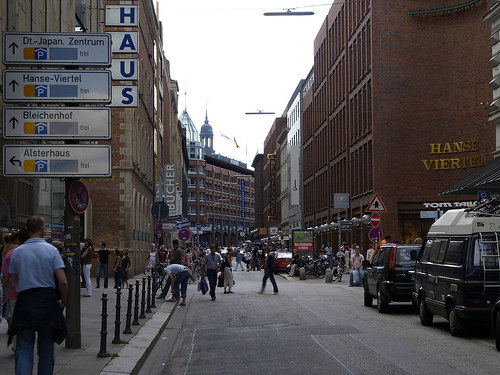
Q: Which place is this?
A: It is a street.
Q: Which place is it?
A: It is a street.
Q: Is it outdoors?
A: Yes, it is outdoors.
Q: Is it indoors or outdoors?
A: It is outdoors.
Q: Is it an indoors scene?
A: No, it is outdoors.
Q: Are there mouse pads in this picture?
A: No, there are no mouse pads.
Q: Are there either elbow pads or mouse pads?
A: No, there are no mouse pads or elbow pads.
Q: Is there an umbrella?
A: No, there are no umbrellas.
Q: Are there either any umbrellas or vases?
A: No, there are no umbrellas or vases.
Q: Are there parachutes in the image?
A: No, there are no parachutes.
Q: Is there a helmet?
A: No, there are no helmets.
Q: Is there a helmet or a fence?
A: No, there are no helmets or fences.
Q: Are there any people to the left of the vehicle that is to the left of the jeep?
A: Yes, there is a person to the left of the vehicle.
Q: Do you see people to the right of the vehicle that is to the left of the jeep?
A: No, the person is to the left of the vehicle.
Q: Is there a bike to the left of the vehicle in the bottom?
A: No, there is a person to the left of the vehicle.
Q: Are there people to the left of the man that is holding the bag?
A: Yes, there is a person to the left of the man.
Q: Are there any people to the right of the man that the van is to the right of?
A: No, the person is to the left of the man.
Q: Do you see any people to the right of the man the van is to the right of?
A: No, the person is to the left of the man.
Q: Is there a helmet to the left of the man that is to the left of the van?
A: No, there is a person to the left of the man.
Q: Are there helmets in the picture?
A: No, there are no helmets.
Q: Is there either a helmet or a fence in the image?
A: No, there are no helmets or fences.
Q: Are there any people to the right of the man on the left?
A: Yes, there is a person to the right of the man.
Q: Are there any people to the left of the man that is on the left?
A: No, the person is to the right of the man.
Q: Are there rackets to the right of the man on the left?
A: No, there is a person to the right of the man.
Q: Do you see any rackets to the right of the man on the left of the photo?
A: No, there is a person to the right of the man.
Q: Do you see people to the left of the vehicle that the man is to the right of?
A: Yes, there is a person to the left of the vehicle.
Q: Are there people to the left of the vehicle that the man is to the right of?
A: Yes, there is a person to the left of the vehicle.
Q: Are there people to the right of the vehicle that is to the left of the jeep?
A: No, the person is to the left of the vehicle.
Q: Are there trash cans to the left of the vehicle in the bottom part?
A: No, there is a person to the left of the vehicle.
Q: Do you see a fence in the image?
A: No, there are no fences.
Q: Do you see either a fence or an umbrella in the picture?
A: No, there are no fences or umbrellas.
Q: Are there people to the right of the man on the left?
A: Yes, there are people to the right of the man.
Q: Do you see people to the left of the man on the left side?
A: No, the people are to the right of the man.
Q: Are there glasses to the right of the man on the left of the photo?
A: No, there are people to the right of the man.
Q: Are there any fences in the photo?
A: No, there are no fences.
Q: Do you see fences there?
A: No, there are no fences.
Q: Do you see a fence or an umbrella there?
A: No, there are no fences or umbrellas.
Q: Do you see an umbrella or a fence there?
A: No, there are no fences or umbrellas.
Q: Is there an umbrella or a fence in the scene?
A: No, there are no fences or umbrellas.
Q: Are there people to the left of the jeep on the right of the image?
A: Yes, there are people to the left of the jeep.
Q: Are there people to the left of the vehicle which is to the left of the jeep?
A: Yes, there are people to the left of the vehicle.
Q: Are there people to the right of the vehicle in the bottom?
A: No, the people are to the left of the vehicle.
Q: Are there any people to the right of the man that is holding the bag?
A: No, the people are to the left of the man.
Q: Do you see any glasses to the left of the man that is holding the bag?
A: No, there are people to the left of the man.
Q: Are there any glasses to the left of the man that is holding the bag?
A: No, there are people to the left of the man.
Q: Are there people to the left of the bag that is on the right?
A: Yes, there are people to the left of the bag.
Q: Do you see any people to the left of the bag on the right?
A: Yes, there are people to the left of the bag.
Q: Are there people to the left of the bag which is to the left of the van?
A: Yes, there are people to the left of the bag.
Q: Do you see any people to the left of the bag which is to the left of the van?
A: Yes, there are people to the left of the bag.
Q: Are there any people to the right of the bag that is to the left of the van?
A: No, the people are to the left of the bag.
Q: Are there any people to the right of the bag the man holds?
A: No, the people are to the left of the bag.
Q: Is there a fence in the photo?
A: No, there are no fences.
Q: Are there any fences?
A: No, there are no fences.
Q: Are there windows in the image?
A: Yes, there is a window.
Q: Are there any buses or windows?
A: Yes, there is a window.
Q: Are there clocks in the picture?
A: No, there are no clocks.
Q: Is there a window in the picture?
A: Yes, there is a window.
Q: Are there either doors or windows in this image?
A: Yes, there is a window.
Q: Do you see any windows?
A: Yes, there is a window.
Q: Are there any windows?
A: Yes, there is a window.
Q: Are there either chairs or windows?
A: Yes, there is a window.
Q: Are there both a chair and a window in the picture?
A: No, there is a window but no chairs.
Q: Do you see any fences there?
A: No, there are no fences.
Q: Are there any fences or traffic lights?
A: No, there are no fences or traffic lights.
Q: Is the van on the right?
A: Yes, the van is on the right of the image.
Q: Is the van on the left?
A: No, the van is on the right of the image.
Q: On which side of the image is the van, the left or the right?
A: The van is on the right of the image.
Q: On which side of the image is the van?
A: The van is on the right of the image.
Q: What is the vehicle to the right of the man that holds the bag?
A: The vehicle is a van.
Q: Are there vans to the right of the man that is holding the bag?
A: Yes, there is a van to the right of the man.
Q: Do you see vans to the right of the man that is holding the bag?
A: Yes, there is a van to the right of the man.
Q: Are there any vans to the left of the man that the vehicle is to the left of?
A: No, the van is to the right of the man.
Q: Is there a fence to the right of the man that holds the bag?
A: No, there is a van to the right of the man.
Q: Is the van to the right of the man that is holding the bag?
A: Yes, the van is to the right of the man.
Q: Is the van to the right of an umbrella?
A: No, the van is to the right of the man.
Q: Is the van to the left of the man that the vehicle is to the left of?
A: No, the van is to the right of the man.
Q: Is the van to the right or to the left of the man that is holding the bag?
A: The van is to the right of the man.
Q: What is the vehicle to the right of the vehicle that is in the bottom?
A: The vehicle is a van.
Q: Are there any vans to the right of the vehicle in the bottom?
A: Yes, there is a van to the right of the vehicle.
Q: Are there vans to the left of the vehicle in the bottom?
A: No, the van is to the right of the vehicle.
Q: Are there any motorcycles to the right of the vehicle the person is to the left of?
A: No, there is a van to the right of the vehicle.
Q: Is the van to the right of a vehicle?
A: Yes, the van is to the right of a vehicle.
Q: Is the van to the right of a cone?
A: No, the van is to the right of a vehicle.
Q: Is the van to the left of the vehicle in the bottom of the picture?
A: No, the van is to the right of the vehicle.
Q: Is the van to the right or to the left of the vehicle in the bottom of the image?
A: The van is to the right of the vehicle.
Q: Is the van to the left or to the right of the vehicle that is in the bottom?
A: The van is to the right of the vehicle.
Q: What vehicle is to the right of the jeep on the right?
A: The vehicle is a van.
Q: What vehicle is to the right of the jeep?
A: The vehicle is a van.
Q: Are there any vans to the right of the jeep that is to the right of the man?
A: Yes, there is a van to the right of the jeep.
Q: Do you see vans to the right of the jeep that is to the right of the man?
A: Yes, there is a van to the right of the jeep.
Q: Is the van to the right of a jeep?
A: Yes, the van is to the right of a jeep.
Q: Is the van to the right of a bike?
A: No, the van is to the right of a jeep.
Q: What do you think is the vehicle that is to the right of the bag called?
A: The vehicle is a van.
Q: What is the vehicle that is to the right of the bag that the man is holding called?
A: The vehicle is a van.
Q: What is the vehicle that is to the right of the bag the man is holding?
A: The vehicle is a van.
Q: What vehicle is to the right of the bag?
A: The vehicle is a van.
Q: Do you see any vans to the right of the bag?
A: Yes, there is a van to the right of the bag.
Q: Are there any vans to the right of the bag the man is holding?
A: Yes, there is a van to the right of the bag.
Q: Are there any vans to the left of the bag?
A: No, the van is to the right of the bag.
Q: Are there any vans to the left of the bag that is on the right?
A: No, the van is to the right of the bag.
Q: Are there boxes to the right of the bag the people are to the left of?
A: No, there is a van to the right of the bag.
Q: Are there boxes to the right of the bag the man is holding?
A: No, there is a van to the right of the bag.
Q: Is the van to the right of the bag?
A: Yes, the van is to the right of the bag.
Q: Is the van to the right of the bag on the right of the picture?
A: Yes, the van is to the right of the bag.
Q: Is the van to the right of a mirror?
A: No, the van is to the right of the bag.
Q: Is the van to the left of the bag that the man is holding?
A: No, the van is to the right of the bag.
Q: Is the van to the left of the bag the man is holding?
A: No, the van is to the right of the bag.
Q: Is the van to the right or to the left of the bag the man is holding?
A: The van is to the right of the bag.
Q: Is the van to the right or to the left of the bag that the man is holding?
A: The van is to the right of the bag.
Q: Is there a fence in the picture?
A: No, there are no fences.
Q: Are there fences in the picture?
A: No, there are no fences.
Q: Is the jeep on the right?
A: Yes, the jeep is on the right of the image.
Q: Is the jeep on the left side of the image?
A: No, the jeep is on the right of the image.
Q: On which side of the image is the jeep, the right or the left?
A: The jeep is on the right of the image.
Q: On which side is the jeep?
A: The jeep is on the right of the image.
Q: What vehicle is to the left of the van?
A: The vehicle is a jeep.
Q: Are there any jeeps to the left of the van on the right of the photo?
A: Yes, there is a jeep to the left of the van.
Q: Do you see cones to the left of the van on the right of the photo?
A: No, there is a jeep to the left of the van.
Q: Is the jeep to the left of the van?
A: Yes, the jeep is to the left of the van.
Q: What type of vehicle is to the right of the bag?
A: The vehicle is a jeep.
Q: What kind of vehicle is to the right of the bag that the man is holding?
A: The vehicle is a jeep.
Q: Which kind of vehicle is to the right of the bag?
A: The vehicle is a jeep.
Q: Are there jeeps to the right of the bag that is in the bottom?
A: Yes, there is a jeep to the right of the bag.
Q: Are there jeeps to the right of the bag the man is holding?
A: Yes, there is a jeep to the right of the bag.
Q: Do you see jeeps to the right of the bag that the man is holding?
A: Yes, there is a jeep to the right of the bag.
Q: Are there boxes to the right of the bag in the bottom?
A: No, there is a jeep to the right of the bag.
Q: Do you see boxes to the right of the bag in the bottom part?
A: No, there is a jeep to the right of the bag.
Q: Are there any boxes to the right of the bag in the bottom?
A: No, there is a jeep to the right of the bag.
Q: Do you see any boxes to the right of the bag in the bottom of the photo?
A: No, there is a jeep to the right of the bag.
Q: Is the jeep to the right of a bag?
A: Yes, the jeep is to the right of a bag.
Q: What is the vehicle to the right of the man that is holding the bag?
A: The vehicle is a jeep.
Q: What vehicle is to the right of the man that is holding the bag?
A: The vehicle is a jeep.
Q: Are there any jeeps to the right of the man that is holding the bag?
A: Yes, there is a jeep to the right of the man.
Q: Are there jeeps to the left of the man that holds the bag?
A: No, the jeep is to the right of the man.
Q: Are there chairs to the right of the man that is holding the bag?
A: No, there is a jeep to the right of the man.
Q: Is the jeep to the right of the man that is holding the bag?
A: Yes, the jeep is to the right of the man.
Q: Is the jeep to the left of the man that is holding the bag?
A: No, the jeep is to the right of the man.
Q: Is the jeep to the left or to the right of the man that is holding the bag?
A: The jeep is to the right of the man.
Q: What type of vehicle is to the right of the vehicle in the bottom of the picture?
A: The vehicle is a jeep.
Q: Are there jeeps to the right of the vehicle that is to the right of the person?
A: Yes, there is a jeep to the right of the vehicle.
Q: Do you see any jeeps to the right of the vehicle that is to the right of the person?
A: Yes, there is a jeep to the right of the vehicle.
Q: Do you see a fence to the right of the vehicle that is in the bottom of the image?
A: No, there is a jeep to the right of the vehicle.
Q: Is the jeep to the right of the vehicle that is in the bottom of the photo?
A: Yes, the jeep is to the right of the vehicle.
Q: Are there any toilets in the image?
A: No, there are no toilets.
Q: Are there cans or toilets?
A: No, there are no toilets or cans.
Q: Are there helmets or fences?
A: No, there are no fences or helmets.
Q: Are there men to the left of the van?
A: Yes, there is a man to the left of the van.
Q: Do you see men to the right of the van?
A: No, the man is to the left of the van.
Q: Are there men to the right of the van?
A: No, the man is to the left of the van.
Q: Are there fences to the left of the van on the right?
A: No, there is a man to the left of the van.